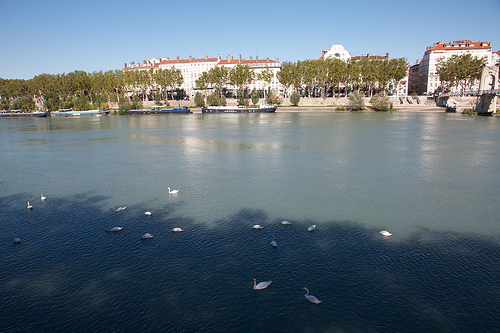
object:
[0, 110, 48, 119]
boat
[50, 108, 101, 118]
boat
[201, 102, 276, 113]
boat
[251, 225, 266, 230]
bird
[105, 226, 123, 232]
bird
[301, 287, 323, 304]
bird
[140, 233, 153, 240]
bird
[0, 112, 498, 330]
canal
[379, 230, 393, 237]
bird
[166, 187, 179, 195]
bird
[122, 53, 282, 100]
white building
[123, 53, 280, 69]
red roof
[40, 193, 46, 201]
bird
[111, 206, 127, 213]
bird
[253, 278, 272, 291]
bird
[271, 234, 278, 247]
bird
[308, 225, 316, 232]
bird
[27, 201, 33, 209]
bird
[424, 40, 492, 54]
building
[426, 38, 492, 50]
roof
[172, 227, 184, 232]
bird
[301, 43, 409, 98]
buildings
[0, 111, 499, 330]
water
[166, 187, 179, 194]
neck